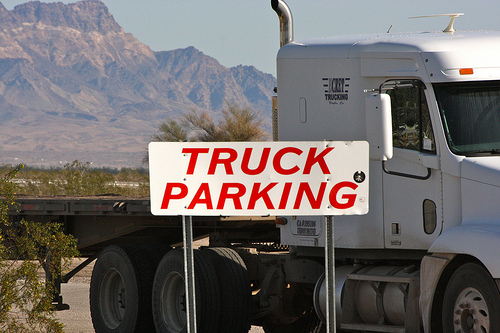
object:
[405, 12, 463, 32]
antenna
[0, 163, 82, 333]
bush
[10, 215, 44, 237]
green leaves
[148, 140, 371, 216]
sign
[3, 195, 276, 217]
truckbed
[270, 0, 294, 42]
exhaust pipe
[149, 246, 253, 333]
wheels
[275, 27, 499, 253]
cab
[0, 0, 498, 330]
truck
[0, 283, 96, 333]
ground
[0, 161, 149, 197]
grass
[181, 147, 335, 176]
words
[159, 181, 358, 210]
words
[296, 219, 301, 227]
numbers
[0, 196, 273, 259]
rest stop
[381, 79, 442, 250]
door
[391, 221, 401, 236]
handle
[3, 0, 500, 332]
semi truck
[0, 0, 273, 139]
mountain